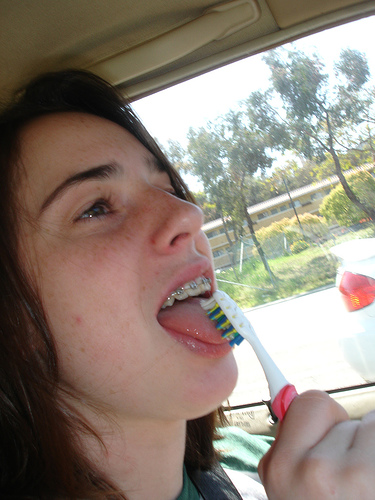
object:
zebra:
[1, 0, 3, 3]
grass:
[212, 247, 339, 312]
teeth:
[161, 275, 211, 309]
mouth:
[156, 259, 238, 360]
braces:
[166, 276, 211, 300]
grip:
[270, 383, 303, 418]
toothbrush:
[199, 289, 299, 419]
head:
[201, 290, 254, 348]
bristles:
[200, 296, 244, 347]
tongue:
[159, 296, 226, 343]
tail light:
[339, 271, 375, 313]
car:
[334, 239, 375, 382]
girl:
[3, 65, 375, 500]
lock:
[262, 399, 279, 422]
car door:
[107, 20, 374, 444]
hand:
[257, 389, 374, 498]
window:
[121, 15, 373, 402]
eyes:
[74, 197, 116, 224]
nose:
[143, 186, 204, 253]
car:
[1, 1, 374, 500]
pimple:
[76, 316, 83, 324]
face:
[13, 117, 238, 418]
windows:
[204, 186, 329, 247]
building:
[203, 162, 375, 277]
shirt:
[175, 426, 276, 500]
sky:
[129, 21, 372, 183]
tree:
[189, 111, 280, 293]